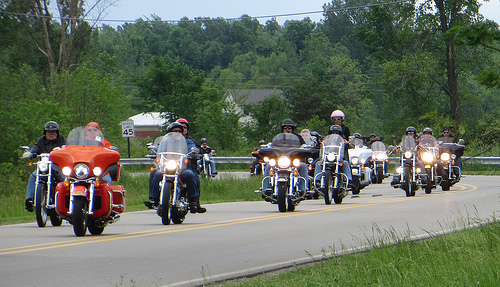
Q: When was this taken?
A: During the day.